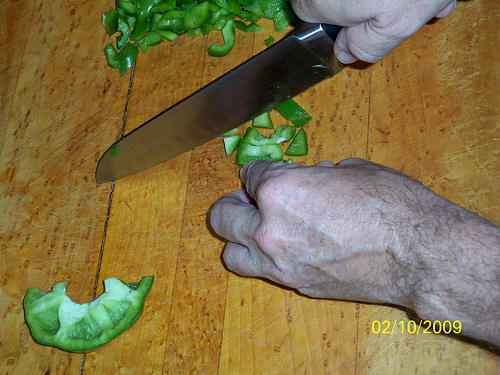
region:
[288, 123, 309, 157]
A piece of green paprica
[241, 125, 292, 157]
A piece of green paprica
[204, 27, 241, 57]
A piece of green paprica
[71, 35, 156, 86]
A piece of green paprica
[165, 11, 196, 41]
A piece of green paprica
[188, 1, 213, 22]
A piece of green paprica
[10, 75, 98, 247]
A brown choping board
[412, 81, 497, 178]
A brown choping board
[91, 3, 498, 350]
Man chopping bell peppers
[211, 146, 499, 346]
Man's hairy wrist and arm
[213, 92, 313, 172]
Small pile of chopped green bell peppers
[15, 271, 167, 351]
Half of a slice of green bell pepper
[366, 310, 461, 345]
Date this picture was taken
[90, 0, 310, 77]
Big pile of chopped green bell peppers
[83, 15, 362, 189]
Large sharp metal knife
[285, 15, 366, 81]
Chrome and black handle on a knife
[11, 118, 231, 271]
Many cuts on a cutting table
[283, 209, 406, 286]
Veins popping out of a man's hand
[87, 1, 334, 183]
A big silver knife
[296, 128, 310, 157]
A piece of green papricca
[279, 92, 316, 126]
A piece of green papricca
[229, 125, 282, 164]
A piece of green papricca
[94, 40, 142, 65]
A piece of green papricca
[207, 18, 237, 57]
A piece of green papricca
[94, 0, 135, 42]
A piece of green papricca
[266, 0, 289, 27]
A piece of green papricca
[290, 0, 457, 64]
the right hand holding the knife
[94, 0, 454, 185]
the long silver knife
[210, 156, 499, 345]
the left hand holding vegetables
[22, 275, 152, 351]
the piece of cut green bell pepper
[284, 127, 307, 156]
the piece of the cut green bell pepper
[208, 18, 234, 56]
the piece of the cut green bell pepper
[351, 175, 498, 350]
the hair on the left arm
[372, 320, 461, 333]
the date stamp near the left arm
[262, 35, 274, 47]
the piece of the cut green bell pepper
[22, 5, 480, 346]
Hands cutting up bell pepper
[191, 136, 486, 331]
Left hand holding pepper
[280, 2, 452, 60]
Right hand holding knife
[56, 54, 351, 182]
Silver blade of knife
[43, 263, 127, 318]
White membrane of pepper slice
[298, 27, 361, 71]
Black handle of knife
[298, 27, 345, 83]
Silver trim between handle and blade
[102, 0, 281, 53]
Chopped bell pepper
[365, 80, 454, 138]
Light brown chopping block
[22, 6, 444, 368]
a man preparing food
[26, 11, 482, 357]
a person cutting food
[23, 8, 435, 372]
vegetables being prepared on chopping board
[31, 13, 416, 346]
green peppers getting cut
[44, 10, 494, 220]
a knife being help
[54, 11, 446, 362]
a wooden chopping board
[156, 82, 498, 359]
hand in the background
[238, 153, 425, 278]
left hand on the table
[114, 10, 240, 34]
a lot cut a green paprika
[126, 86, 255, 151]
silver metal knife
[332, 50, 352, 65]
thumb of the right hand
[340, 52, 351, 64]
white nail thumb of the right hand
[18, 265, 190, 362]
piece of cut green pepper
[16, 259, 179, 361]
piece of cut green pepper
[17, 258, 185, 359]
piece of cut green pepper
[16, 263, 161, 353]
piece of cut green pepper